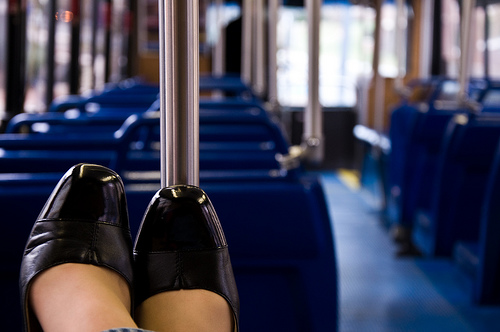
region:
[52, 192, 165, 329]
These are shoes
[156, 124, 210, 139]
This is a pole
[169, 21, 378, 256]
This is a bus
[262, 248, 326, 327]
These are plastic seats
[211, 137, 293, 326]
The seats are made of plastic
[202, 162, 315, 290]
The seats are dark blue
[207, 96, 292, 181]
This is a handle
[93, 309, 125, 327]
These are blue jeans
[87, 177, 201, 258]
The shoes are flats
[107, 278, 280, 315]
The shoes are shiny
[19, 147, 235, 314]
a woman is wearing black pumps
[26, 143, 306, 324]
she is resting her feet on the seat in front of her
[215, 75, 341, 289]
the mode of transportation has blue seats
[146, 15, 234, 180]
a pole is in front of the woman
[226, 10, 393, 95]
the transportation's window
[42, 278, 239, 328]
the top of the woman's feet are visible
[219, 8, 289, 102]
a person is standing up by the window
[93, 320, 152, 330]
the bottom of the woman's jeans can be seen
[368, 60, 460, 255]
another person is sitting in a seat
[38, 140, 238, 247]
the toe of the shoe is shiny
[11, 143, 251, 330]
shoes on a woman's feet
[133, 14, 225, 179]
metal pole on a bus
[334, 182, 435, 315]
middle walkway on a bus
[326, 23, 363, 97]
front window of a bus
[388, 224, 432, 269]
legs of a seat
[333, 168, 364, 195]
yellow line by bus entrance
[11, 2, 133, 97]
side windows of a bus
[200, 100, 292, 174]
handle on top of seats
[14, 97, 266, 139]
Blue seat on a bus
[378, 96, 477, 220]
Blue seat on a bus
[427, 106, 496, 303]
Blue seat on a bus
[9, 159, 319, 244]
Blue seat on a bus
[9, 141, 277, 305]
Reflective black shoes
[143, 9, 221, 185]
Tall silver pole on a bus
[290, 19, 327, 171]
Tall silver pole on a bus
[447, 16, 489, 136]
Tall silver pole on a bus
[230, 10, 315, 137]
Tall silver pole on a bus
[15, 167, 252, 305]
Her shoes are black.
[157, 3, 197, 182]
The pole is silver.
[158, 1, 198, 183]
The pole is metal.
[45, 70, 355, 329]
The seats are blue.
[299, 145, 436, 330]
The ground is blue.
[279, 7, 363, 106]
The sun is shining through.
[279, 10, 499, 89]
The windows are all over.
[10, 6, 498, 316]
The bus is empty.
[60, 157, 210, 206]
The lights are shining.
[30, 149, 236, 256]
Her shoes are shiny.